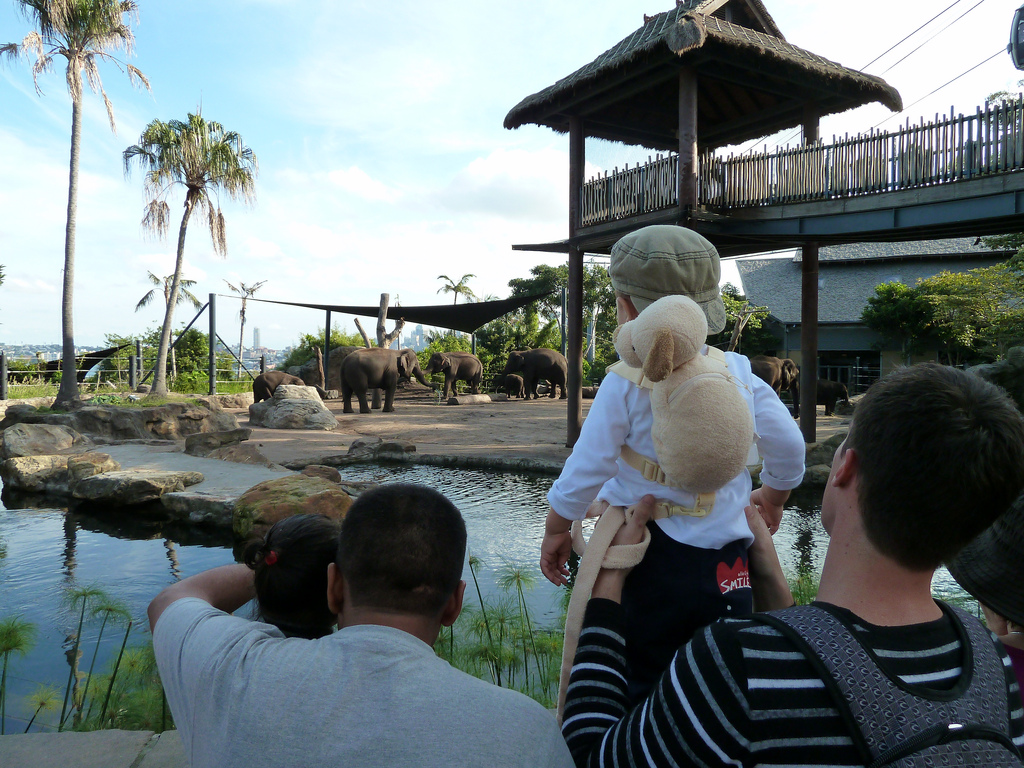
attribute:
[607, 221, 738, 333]
hat — green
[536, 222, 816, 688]
child — young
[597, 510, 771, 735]
pants — black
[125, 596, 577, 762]
shirt — white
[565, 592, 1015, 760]
shirt — white